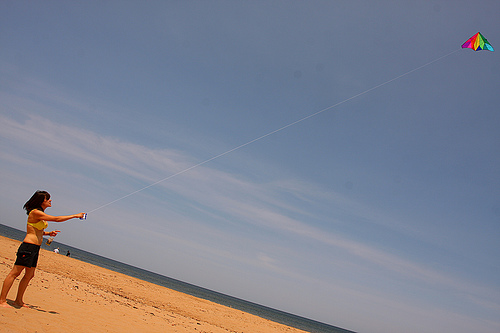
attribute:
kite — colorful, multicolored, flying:
[460, 30, 495, 58]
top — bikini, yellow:
[25, 218, 49, 235]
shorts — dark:
[14, 241, 40, 266]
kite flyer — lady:
[0, 190, 87, 309]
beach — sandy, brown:
[56, 236, 353, 332]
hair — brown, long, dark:
[23, 189, 52, 210]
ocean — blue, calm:
[71, 246, 358, 331]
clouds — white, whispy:
[0, 110, 199, 192]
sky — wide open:
[0, 1, 461, 190]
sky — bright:
[137, 58, 499, 271]